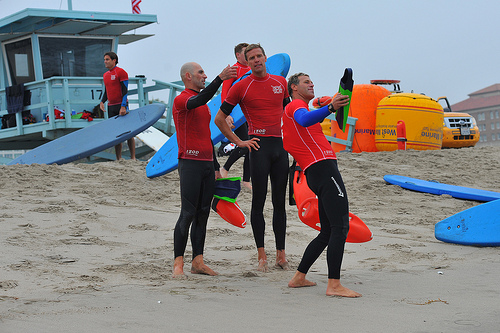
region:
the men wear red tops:
[175, 71, 340, 168]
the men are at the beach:
[0, 0, 497, 330]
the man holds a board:
[8, 101, 165, 166]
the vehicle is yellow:
[433, 95, 479, 146]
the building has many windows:
[461, 109, 498, 142]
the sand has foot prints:
[0, 146, 499, 330]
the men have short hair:
[248, 44, 313, 94]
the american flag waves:
[128, 0, 142, 12]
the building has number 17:
[89, 89, 104, 100]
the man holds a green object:
[330, 68, 354, 127]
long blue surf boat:
[13, 102, 164, 160]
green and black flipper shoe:
[334, 65, 354, 128]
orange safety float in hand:
[298, 196, 373, 243]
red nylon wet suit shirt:
[172, 88, 216, 161]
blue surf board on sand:
[385, 172, 499, 203]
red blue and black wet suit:
[282, 98, 364, 279]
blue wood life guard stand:
[0, 8, 185, 140]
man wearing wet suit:
[214, 45, 291, 267]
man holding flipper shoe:
[172, 62, 235, 275]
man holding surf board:
[5, 53, 165, 166]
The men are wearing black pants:
[173, 150, 365, 293]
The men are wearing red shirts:
[95, 62, 367, 179]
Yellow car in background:
[432, 89, 482, 149]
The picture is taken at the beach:
[8, 158, 493, 325]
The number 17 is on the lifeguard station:
[80, 82, 107, 106]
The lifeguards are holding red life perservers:
[218, 173, 380, 246]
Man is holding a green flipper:
[324, 61, 356, 133]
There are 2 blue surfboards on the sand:
[382, 160, 495, 258]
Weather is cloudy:
[152, 9, 490, 90]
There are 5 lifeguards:
[83, 37, 369, 164]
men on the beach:
[87, 51, 469, 277]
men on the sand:
[144, 13, 450, 326]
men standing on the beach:
[130, 31, 378, 331]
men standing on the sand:
[159, 11, 421, 265]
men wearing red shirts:
[126, 31, 411, 298]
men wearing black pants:
[134, 37, 472, 310]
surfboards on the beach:
[44, 39, 404, 293]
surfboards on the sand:
[30, 18, 497, 315]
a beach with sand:
[49, 43, 419, 326]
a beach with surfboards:
[36, 51, 486, 277]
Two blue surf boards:
[385, 158, 498, 250]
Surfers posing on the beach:
[144, 18, 400, 310]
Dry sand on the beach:
[0, 151, 498, 331]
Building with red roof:
[419, 73, 499, 145]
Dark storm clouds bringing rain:
[0, 6, 499, 108]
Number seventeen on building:
[81, 73, 106, 108]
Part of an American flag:
[120, 0, 168, 29]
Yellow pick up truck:
[435, 94, 490, 160]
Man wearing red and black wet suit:
[89, 46, 134, 164]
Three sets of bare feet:
[165, 233, 385, 299]